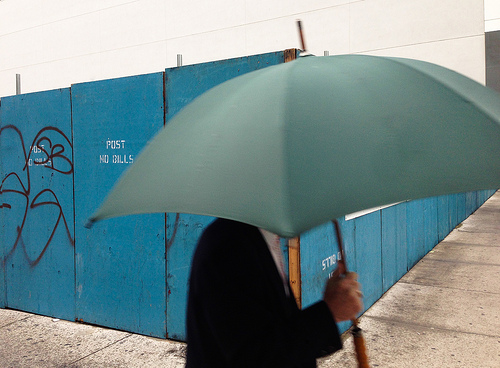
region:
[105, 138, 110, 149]
white letter stenciled on wall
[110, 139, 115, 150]
white letter stenciled on wall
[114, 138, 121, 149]
white letter stenciled on wall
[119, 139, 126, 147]
white letter stenciled on wall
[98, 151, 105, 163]
white letter stenciled on wall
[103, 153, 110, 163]
white letter stenciled on wall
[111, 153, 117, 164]
white letter stenciled on wall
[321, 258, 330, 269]
white letter stenciled on wall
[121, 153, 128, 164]
white letter stenciled on wall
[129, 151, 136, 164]
white letter stenciled on wall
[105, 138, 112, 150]
white letter stencil on wall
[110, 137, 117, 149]
white letter stencil on wall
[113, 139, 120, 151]
white letter stencil on wall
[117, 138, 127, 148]
white letter stencil on wall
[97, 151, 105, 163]
white letter stencil on wall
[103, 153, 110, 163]
white letter stencil on wall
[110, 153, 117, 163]
white letter stencil on wall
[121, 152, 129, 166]
white letter stencil on wall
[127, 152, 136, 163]
white letter stencil on wall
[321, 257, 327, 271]
white letter stencil on wall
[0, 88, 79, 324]
blue wooden wall board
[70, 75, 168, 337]
blue wooden wall board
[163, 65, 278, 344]
blue wooden wall board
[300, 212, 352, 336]
blue wooden wall board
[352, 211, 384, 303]
blue wooden wall board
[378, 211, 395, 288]
blue wooden wall board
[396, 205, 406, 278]
blue wooden wall board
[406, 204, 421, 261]
blue wooden wall board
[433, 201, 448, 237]
blue wooden wall board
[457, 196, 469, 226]
blue wooden wall board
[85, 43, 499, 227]
a navy blue umbrella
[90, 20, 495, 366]
an umbrella with a wooden handle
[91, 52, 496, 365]
a man clutching a blue umbrella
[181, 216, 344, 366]
a man in a suit and tie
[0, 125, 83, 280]
graffiti on a wall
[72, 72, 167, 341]
a large blue wall with writing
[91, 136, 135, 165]
writing on a blue wall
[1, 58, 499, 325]
a long blue wall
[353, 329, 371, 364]
a wooden umbrella handle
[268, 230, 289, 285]
a red tie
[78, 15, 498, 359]
A man holding an umbrella